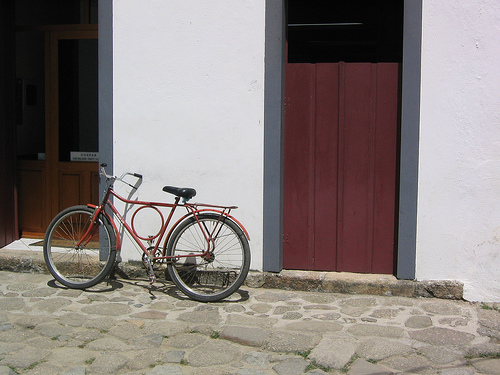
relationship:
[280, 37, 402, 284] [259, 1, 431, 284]
lines on door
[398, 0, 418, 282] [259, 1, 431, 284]
edges at door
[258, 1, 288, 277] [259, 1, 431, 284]
edges at door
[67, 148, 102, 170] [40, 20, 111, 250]
plate on door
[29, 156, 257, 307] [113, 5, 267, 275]
bike close walls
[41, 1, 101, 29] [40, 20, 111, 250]
space above door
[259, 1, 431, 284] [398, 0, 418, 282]
door with edges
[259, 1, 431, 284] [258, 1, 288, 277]
door with edges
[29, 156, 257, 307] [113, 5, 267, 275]
bike against walls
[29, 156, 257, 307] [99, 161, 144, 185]
bike with bars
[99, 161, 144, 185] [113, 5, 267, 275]
bars against walls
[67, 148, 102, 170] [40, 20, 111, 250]
plate in door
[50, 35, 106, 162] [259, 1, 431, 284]
glass in door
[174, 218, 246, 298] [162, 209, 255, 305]
spokes in tire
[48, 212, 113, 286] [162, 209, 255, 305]
spokes in tire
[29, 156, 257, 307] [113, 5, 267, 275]
bike next walls